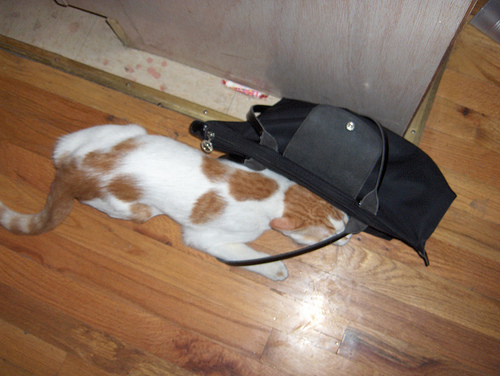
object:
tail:
[0, 172, 88, 235]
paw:
[261, 257, 289, 283]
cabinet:
[104, 0, 471, 138]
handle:
[193, 154, 357, 270]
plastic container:
[467, 0, 499, 48]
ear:
[266, 217, 303, 235]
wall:
[1, 0, 475, 140]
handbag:
[187, 96, 455, 268]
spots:
[186, 187, 232, 227]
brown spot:
[228, 164, 279, 201]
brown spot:
[198, 150, 228, 185]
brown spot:
[104, 168, 146, 205]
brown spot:
[77, 141, 119, 173]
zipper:
[195, 124, 428, 270]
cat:
[0, 124, 352, 282]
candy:
[220, 79, 270, 102]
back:
[144, 138, 299, 222]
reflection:
[269, 268, 356, 362]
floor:
[0, 13, 499, 375]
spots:
[140, 67, 164, 80]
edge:
[103, 17, 153, 58]